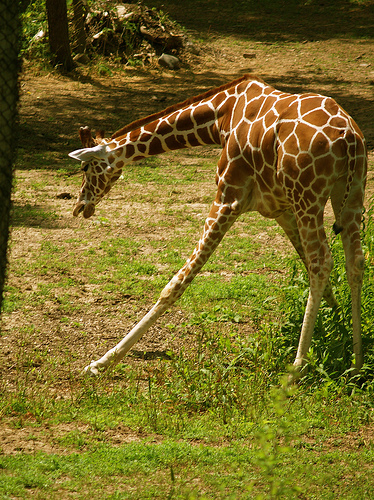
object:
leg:
[284, 215, 332, 370]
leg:
[332, 195, 371, 372]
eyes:
[78, 161, 91, 175]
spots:
[291, 117, 319, 153]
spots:
[228, 116, 254, 152]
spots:
[294, 91, 330, 119]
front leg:
[84, 200, 230, 372]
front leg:
[269, 207, 341, 316]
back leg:
[291, 205, 333, 375]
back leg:
[339, 183, 373, 373]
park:
[19, 6, 362, 494]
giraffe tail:
[333, 143, 362, 239]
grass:
[323, 432, 372, 495]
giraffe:
[12, 79, 365, 388]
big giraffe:
[66, 66, 368, 382]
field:
[14, 0, 373, 498]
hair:
[103, 68, 269, 137]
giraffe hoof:
[78, 360, 109, 377]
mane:
[110, 71, 269, 139]